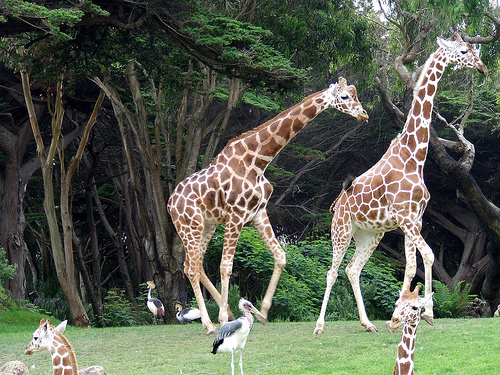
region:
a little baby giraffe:
[16, 306, 106, 372]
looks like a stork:
[206, 295, 284, 371]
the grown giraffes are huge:
[153, 22, 487, 345]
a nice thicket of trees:
[27, 35, 272, 288]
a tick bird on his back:
[339, 170, 359, 199]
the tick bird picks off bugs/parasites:
[336, 170, 368, 202]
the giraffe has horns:
[321, 63, 382, 130]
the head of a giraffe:
[425, 30, 491, 75]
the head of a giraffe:
[325, 77, 372, 122]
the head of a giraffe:
[17, 317, 71, 362]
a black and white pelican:
[209, 294, 266, 365]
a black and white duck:
[171, 299, 205, 325]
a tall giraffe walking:
[162, 74, 373, 333]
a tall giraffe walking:
[308, 33, 490, 330]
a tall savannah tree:
[1, 1, 122, 333]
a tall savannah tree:
[95, 2, 234, 324]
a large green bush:
[197, 216, 436, 331]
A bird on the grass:
[203, 298, 268, 374]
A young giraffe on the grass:
[379, 278, 429, 373]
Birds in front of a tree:
[138, 276, 202, 325]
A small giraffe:
[21, 317, 91, 374]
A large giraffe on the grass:
[169, 60, 367, 330]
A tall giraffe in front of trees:
[162, 58, 365, 337]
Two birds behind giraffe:
[134, 273, 211, 322]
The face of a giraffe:
[327, 78, 370, 123]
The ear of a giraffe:
[433, 35, 450, 47]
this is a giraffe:
[160, 70, 371, 324]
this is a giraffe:
[27, 304, 83, 374]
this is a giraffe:
[309, 36, 488, 341]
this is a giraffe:
[378, 273, 431, 373]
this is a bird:
[197, 287, 305, 374]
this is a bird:
[167, 287, 217, 349]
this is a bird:
[135, 274, 178, 336]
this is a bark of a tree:
[18, 64, 98, 338]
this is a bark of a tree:
[124, 97, 189, 302]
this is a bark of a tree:
[437, 138, 498, 219]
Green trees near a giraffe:
[18, 12, 241, 102]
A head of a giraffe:
[24, 320, 76, 372]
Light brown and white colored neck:
[53, 347, 68, 372]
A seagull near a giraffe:
[213, 297, 266, 374]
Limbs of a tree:
[23, 87, 96, 157]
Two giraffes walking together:
[186, 32, 498, 276]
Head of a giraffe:
[383, 282, 430, 372]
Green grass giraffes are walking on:
[283, 342, 353, 368]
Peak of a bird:
[252, 307, 263, 315]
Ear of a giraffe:
[42, 320, 49, 330]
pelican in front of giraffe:
[208, 297, 267, 374]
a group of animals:
[13, 26, 491, 373]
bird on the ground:
[188, 285, 264, 374]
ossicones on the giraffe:
[328, 65, 356, 95]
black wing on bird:
[208, 311, 248, 338]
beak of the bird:
[245, 300, 263, 326]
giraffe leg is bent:
[253, 206, 288, 316]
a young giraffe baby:
[17, 309, 93, 374]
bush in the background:
[213, 209, 410, 334]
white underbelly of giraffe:
[346, 220, 381, 242]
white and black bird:
[189, 294, 279, 371]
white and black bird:
[206, 288, 274, 366]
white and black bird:
[189, 288, 272, 373]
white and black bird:
[209, 292, 275, 374]